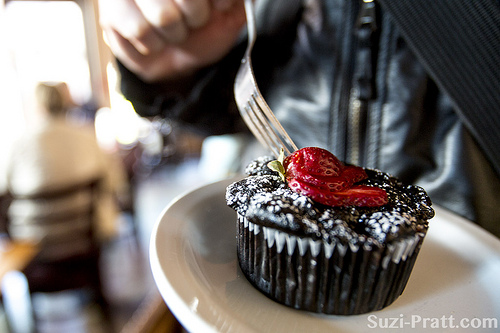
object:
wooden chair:
[0, 174, 124, 333]